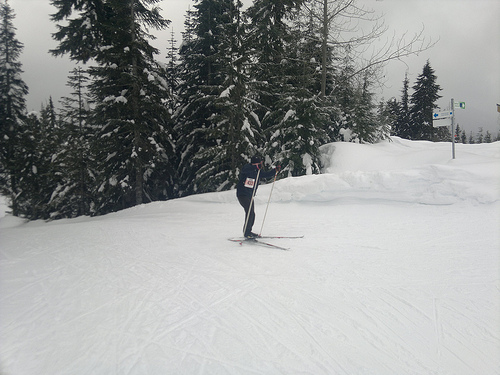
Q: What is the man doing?
A: Skating.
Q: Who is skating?
A: The man.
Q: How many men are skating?
A: 1.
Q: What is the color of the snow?
A: White.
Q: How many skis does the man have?
A: 2.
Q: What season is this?
A: Winter.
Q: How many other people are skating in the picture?
A: 0.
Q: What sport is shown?
A: Skiing.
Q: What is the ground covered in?
A: Snow.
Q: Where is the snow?
A: On the ground.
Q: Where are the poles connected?
A: To pole.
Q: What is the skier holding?
A: Poles.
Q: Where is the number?
A: On skier's bib.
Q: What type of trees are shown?
A: Pine trees.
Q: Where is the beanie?
A: On skier.